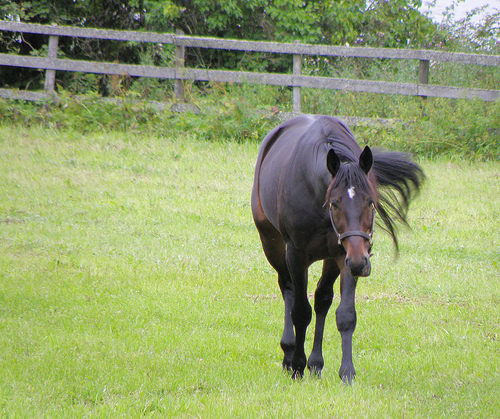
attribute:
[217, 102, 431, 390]
horse — walking, black, brown, field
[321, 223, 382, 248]
harness — leather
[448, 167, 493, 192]
grass — green, tall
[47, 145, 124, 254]
field — grassy, green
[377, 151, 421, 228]
tail — black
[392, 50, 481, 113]
fence — wooden, gray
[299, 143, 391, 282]
head — black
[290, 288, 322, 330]
knee — front left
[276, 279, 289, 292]
knee — back left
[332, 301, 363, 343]
knee — front right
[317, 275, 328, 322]
knee — back right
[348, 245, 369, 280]
nose — brown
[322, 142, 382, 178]
ears — brown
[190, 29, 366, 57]
rail — top